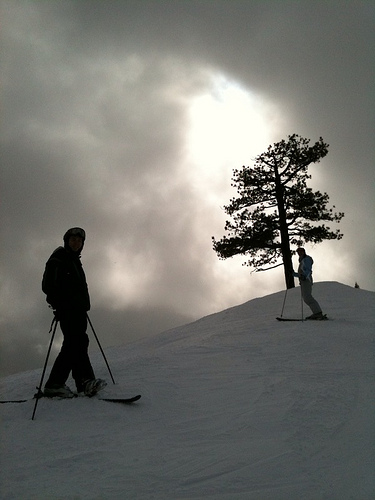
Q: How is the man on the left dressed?
A: In black.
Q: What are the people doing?
A: Skiing.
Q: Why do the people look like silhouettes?
A: More light behind than in front.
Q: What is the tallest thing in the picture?
A: A tree.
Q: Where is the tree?
A: Top of a hill.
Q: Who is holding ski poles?
A: Both skiers.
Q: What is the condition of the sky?
A: It is dark.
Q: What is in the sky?
A: Clouds.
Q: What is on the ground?
A: Snow.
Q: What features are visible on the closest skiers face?
A: No features are visible.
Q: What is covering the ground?
A: Snow.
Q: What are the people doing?
A: Skiing.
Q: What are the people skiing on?
A: Hill.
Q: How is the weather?
A: Cloudy.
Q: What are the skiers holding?
A: Poles.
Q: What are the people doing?
A: Skiing.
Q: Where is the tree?
A: On top of the hill.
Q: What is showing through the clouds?
A: The sun.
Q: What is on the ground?
A: Snow.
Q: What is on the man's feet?
A: Skis.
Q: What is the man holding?
A: Ski poles.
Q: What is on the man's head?
A: Goggles.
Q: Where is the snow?
A: On the ground.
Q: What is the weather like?
A: Cloudy.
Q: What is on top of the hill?
A: A tree.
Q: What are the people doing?
A: Skiing.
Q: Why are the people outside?
A: The people are skiing.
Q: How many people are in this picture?
A: Two.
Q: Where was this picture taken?
A: On a ski slope.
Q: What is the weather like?
A: Cloudy.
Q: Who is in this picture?
A: Two skiers.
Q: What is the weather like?
A: Snowy and cold.